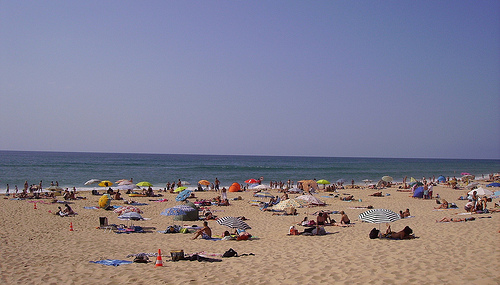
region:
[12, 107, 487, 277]
a busy beach scene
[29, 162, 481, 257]
a lot of beach goers in the area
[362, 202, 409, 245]
a black and white striped umbrella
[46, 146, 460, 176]
wavey water in the background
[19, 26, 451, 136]
clear skies above the area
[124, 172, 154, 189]
a yellow umbrella on the beach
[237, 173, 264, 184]
a red umbrella in the distance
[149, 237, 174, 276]
an orange and white cone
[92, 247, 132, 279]
a blue blanket in the sand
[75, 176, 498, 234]
there are too many people to count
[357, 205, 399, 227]
a black and white striped umbrella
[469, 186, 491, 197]
a white umbrella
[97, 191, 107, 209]
a yellow umbrella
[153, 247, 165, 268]
an orange and white striped cone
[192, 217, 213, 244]
a man sitting on the sand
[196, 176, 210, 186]
an orange umbrella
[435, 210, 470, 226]
a person laying in the sand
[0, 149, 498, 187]
blue ocean water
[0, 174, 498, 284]
a sandy beach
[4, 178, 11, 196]
a person walking alongside the water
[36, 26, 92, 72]
white clouds in blue sky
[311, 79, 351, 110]
white clouds in blue sky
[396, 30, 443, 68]
white clouds in blue sky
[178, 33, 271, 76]
white clouds in blue sky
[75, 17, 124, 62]
white clouds in blue sky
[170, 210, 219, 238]
people sitting on beach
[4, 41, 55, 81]
white clouds in blue sky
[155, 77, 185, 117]
white clouds in blue sky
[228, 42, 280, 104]
white clouds in blue sky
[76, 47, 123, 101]
white clouds in blue sky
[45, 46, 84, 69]
white clouds in blue sky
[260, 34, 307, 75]
white clouds in blue sky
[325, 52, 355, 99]
white clouds in blue sky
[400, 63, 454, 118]
white clouds in blue sky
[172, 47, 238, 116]
white clouds in blue sky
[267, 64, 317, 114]
white clouds in blue sky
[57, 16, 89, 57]
white clouds in blue sky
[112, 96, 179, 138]
white clouds in blue sky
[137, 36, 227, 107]
white clouds in blue sky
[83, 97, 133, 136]
white clouds in blue sky